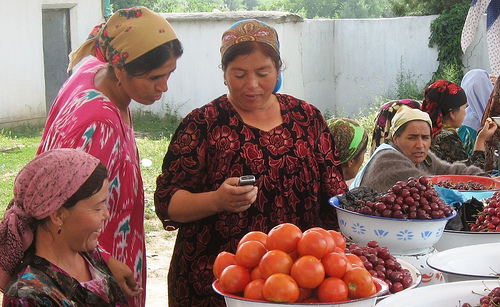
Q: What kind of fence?
A: Wood.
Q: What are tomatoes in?
A: Bowl.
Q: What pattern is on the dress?
A: A floral pattern.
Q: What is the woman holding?
A: A cellphone.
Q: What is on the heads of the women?
A: Hair covers.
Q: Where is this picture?
A: A market.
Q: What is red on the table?
A: Tomatoes.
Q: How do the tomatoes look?
A: Ripe.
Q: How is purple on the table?
A: Grapes.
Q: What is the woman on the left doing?
A: Laughing.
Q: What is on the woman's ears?
A: Black earrings.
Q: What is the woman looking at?
A: A cell phone.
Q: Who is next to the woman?
A: Another woman.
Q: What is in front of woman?
A: Tomatoes.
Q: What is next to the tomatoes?
A: Grapes.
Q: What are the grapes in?
A: A bowl.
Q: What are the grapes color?
A: Purple.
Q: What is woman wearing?
A: A dress.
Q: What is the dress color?
A: Red and black.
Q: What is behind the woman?
A: Grass.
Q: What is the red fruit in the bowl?
A: Tomato.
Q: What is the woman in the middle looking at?
A: A cell phone.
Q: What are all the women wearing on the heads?
A: Scarfs.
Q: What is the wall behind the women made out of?
A: Stone.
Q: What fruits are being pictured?
A: Tomatoes, and grapes.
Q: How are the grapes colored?
A: Purple.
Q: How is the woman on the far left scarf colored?
A: Pink.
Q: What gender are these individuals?
A: Female.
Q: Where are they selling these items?
A: A marketplace.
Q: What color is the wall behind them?
A: White.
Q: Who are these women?
A: Produce merchants.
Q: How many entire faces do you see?
A: 3.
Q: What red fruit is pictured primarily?
A: Tomatoes.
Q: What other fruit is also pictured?
A: Cherries.